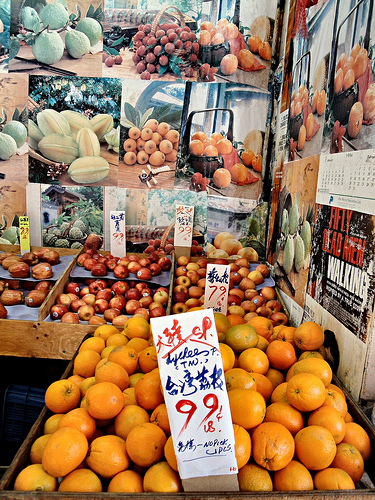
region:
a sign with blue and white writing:
[150, 307, 243, 475]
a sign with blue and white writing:
[203, 264, 229, 315]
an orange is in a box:
[43, 378, 80, 412]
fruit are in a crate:
[72, 233, 173, 283]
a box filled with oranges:
[16, 315, 370, 492]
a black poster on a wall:
[307, 203, 374, 345]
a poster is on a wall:
[269, 151, 324, 310]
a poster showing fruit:
[23, 74, 116, 187]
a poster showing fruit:
[120, 80, 180, 191]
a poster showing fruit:
[180, 81, 264, 202]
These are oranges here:
[300, 386, 325, 430]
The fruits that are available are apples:
[110, 281, 128, 318]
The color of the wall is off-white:
[369, 370, 373, 387]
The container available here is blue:
[11, 388, 23, 420]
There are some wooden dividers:
[45, 284, 57, 323]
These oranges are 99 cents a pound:
[181, 394, 216, 423]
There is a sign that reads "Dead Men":
[324, 232, 364, 259]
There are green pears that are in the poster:
[43, 28, 64, 59]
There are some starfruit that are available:
[42, 109, 66, 157]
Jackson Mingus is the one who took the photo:
[74, 187, 278, 438]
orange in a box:
[294, 420, 339, 460]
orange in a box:
[255, 414, 286, 466]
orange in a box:
[125, 422, 151, 454]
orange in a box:
[92, 435, 129, 469]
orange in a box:
[77, 381, 124, 413]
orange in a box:
[49, 435, 94, 465]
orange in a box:
[108, 345, 138, 368]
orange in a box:
[237, 341, 264, 366]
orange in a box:
[285, 315, 323, 353]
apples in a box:
[78, 288, 156, 308]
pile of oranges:
[236, 348, 362, 490]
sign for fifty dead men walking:
[309, 204, 372, 321]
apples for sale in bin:
[63, 279, 158, 324]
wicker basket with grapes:
[128, 4, 203, 79]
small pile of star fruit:
[28, 93, 115, 183]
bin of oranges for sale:
[95, 307, 265, 490]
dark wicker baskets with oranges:
[183, 105, 239, 181]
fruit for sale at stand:
[75, 238, 279, 424]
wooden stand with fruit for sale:
[7, 238, 124, 357]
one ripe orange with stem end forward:
[285, 371, 327, 411]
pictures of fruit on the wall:
[47, 31, 222, 214]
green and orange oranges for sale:
[232, 327, 327, 438]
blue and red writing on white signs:
[145, 306, 240, 487]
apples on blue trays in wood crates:
[112, 263, 194, 310]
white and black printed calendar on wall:
[299, 130, 364, 213]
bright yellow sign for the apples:
[8, 206, 47, 268]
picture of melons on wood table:
[29, 88, 116, 192]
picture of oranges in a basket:
[185, 91, 266, 210]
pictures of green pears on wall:
[8, 4, 103, 81]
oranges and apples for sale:
[90, 231, 274, 485]